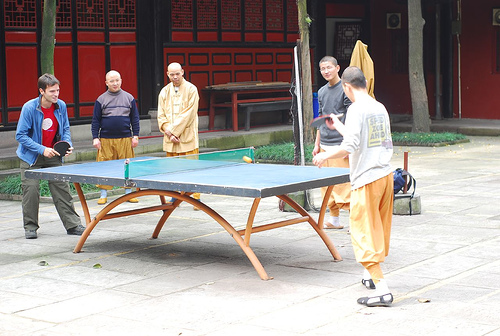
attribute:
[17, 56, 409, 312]
man — playing, watching, wearing, bald, looking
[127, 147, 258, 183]
table tennis net — green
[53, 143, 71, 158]
tennis paddle — red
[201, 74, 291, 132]
table — red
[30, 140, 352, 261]
tennis table — green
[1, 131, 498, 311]
ground — grey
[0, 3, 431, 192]
tree — green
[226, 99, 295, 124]
bench — gray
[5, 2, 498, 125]
wall — red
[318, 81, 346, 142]
shirt — gray